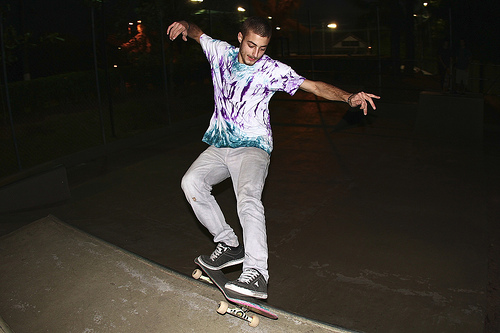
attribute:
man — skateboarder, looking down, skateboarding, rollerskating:
[163, 12, 381, 301]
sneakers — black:
[200, 239, 271, 300]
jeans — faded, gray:
[182, 144, 271, 274]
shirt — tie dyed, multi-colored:
[195, 31, 304, 152]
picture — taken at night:
[0, 1, 497, 331]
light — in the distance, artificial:
[328, 21, 337, 28]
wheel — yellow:
[191, 267, 199, 279]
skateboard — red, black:
[191, 255, 277, 324]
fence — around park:
[1, 10, 116, 157]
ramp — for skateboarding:
[415, 90, 481, 144]